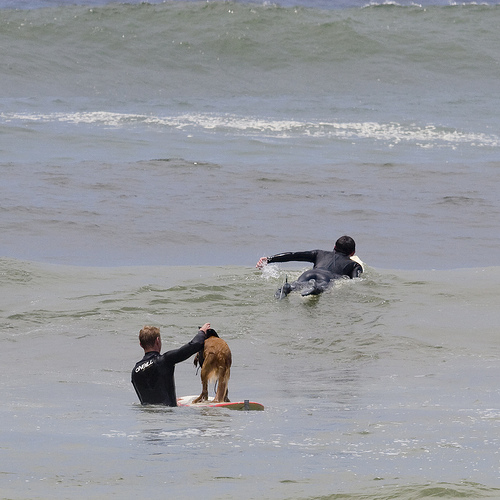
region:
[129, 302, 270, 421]
and man and a dog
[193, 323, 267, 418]
a dog on a surfboard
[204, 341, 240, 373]
a dog with brown fur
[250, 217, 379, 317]
a man laying on a surfboard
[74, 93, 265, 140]
a wave in the ocean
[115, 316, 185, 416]
a man standing in the water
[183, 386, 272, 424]
a red and white surfboard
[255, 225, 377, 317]
a man wearing a wet suit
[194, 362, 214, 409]
the leg of a dog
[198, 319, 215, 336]
a person's hand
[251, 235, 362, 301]
The back of a person surfing at the beach.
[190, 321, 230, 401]
A brown dog standing on a paddle board.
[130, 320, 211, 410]
The torso of a white man in the water.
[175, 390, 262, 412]
A white paddle board with a red strip on it.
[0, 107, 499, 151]
A small wave coming from afar.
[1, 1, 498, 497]
A vast area of ocean water.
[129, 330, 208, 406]
A black wet shirt on the man's back.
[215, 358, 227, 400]
The tail of the brown dog.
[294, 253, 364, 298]
A surfboard used by a young person.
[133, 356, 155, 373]
A message in white as the name of a brand.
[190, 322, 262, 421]
Dog on surfboard bring held up by man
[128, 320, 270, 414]
man holding dog on surfboard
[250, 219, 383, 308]
man paddling out on surfboard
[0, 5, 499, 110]
wave about to break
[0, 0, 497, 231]
ocean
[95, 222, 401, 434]
two guys surfing with dog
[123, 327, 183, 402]
guy in water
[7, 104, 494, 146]
small wave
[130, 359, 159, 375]
lettering on back of wetsuit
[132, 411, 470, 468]
sea foam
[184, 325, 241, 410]
a small brown dog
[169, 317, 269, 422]
a dog stands on a surfboard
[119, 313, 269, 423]
a man holds a dog on a surfboard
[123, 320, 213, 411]
a man in a black wetsuit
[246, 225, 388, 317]
a man paddling through water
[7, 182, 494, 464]
surfers in the ocean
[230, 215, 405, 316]
a man lies on a surfboard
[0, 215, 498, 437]
people riding waves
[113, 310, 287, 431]
a man teaches his dog to surf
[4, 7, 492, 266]
The ocean waves the man on the surfboard is swimming out towards.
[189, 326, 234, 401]
The brown dog standing on the surfboard.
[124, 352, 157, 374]
The white letters on the back of the wetsuit the man standing next to the dog has on.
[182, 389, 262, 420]
The white and red surfboard the dog is standing on.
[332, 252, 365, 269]
The tip of the white surfboard the man is laying on.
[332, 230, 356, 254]
The black hair of the man laying on the surfboard.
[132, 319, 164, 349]
The reddish-blonde hair of the man standing next to the dog on the surfboard.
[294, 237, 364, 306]
The black wet suit the man that is laying on the surfboard is wearing.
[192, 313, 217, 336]
The man's hand on the brown dog.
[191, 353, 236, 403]
The legs of the brown dog.